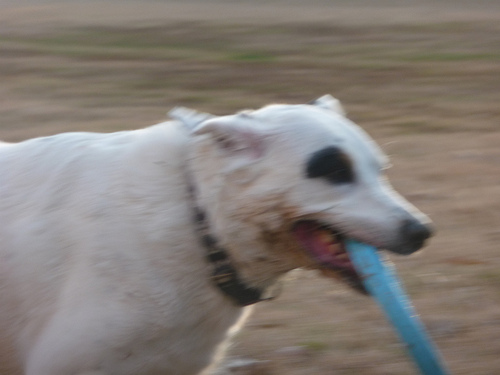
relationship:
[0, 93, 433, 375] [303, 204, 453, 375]
dog holding frisbee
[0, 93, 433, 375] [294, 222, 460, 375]
dog holding frisbee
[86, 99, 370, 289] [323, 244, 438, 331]
dog holding frisbee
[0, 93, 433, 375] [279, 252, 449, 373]
dog holding frisbee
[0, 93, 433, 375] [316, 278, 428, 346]
dog holding frisbee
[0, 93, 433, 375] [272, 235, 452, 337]
dog holding frisbee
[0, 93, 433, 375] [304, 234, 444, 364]
dog holding frisbee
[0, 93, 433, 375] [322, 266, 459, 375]
dog holding frisbee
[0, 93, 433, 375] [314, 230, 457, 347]
dog holding frisbee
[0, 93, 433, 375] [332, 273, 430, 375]
dog holding frisbee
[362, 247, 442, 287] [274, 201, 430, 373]
frisbee on dogs mouth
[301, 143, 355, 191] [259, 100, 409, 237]
eye around dogs eye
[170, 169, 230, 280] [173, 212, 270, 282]
collar around dogs neck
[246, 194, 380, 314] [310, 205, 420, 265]
teeth in dogs mouth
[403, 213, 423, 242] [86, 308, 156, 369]
nose of a dog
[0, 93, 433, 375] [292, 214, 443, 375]
dog carrying a frisbee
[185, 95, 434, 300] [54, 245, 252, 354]
head of  a dog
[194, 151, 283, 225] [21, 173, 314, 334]
right ear of a dog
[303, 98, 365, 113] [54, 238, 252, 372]
left ear of a dog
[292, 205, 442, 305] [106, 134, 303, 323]
mouth of a dog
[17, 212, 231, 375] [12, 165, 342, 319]
only he right side of dog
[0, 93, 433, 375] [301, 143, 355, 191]
dog has eye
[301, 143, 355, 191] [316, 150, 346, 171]
eye over eye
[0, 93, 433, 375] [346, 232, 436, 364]
dog carrying a frisbee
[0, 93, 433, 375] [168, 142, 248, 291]
dog wearing a collar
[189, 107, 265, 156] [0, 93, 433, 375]
ear of dog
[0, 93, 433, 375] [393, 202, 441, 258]
dog has nose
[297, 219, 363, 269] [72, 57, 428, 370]
teeth of dog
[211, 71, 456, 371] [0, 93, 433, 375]
head of a dog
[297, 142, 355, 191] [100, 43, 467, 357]
eye of a dog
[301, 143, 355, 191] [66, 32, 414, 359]
eye of a dog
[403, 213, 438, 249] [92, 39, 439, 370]
nose of a dog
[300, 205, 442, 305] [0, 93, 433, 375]
mouth of a dog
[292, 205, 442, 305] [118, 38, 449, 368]
mouth of a dog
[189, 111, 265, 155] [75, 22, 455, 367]
ear of a dog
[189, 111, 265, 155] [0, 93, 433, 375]
ear of a dog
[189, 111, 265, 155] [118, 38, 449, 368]
ear of a dog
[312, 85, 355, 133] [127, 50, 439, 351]
ear of a dog